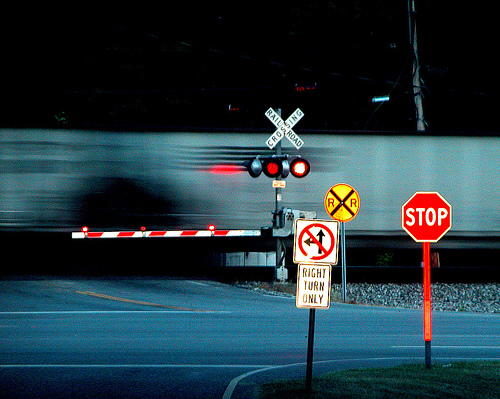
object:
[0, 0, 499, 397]
photo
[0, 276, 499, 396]
paved road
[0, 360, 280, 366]
white lines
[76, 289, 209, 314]
yellow lines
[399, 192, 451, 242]
sign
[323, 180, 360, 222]
sign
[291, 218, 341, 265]
sign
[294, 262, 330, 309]
sign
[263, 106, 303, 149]
sign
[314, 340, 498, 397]
area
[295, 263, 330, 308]
right turn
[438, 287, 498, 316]
gray rocks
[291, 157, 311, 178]
light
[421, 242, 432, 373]
pole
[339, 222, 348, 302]
pole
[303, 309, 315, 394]
pole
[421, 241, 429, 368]
sign pole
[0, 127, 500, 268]
train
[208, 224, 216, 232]
lights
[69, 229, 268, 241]
guard rail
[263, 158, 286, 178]
lights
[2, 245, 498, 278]
railroad